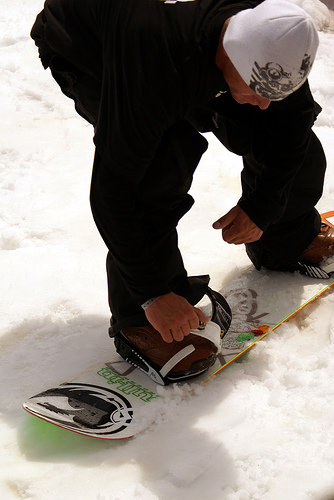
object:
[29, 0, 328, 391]
snowboarder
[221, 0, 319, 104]
cap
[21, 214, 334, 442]
snowboard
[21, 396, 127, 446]
sticker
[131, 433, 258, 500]
reflection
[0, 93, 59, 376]
snow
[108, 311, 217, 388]
boots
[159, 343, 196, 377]
straps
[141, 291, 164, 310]
bracelet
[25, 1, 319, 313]
jacket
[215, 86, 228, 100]
zipper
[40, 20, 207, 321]
pants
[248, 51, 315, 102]
graphics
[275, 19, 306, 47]
seams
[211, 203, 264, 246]
hands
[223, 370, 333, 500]
snow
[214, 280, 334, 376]
edge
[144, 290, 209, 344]
hand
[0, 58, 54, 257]
tracks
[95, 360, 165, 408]
design